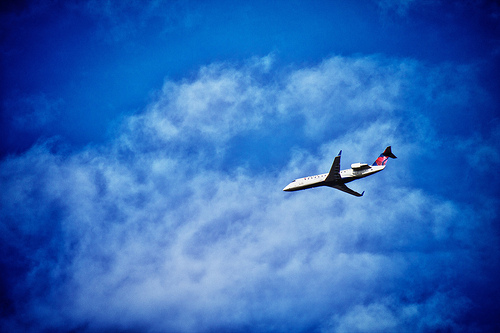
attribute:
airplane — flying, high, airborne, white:
[283, 146, 398, 200]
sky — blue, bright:
[1, 1, 500, 333]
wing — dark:
[327, 149, 341, 181]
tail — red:
[372, 146, 391, 166]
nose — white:
[283, 184, 289, 192]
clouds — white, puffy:
[73, 199, 492, 332]